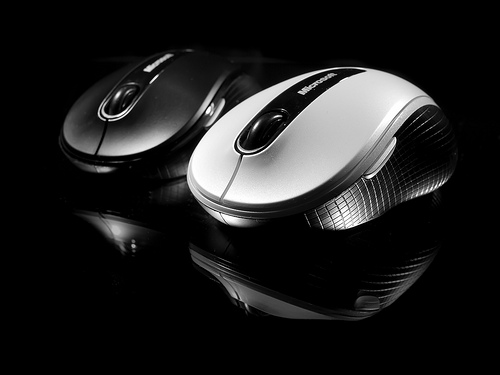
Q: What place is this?
A: It is a display.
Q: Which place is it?
A: It is a display.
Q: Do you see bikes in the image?
A: No, there are no bikes.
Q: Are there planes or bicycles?
A: No, there are no bicycles or planes.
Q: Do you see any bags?
A: No, there are no bags.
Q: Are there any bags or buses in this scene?
A: No, there are no bags or buses.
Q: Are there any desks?
A: Yes, there is a desk.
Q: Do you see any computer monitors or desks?
A: Yes, there is a desk.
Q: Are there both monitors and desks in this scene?
A: No, there is a desk but no monitors.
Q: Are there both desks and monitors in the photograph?
A: No, there is a desk but no monitors.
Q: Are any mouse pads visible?
A: No, there are no mouse pads.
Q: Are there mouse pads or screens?
A: No, there are no mouse pads or screens.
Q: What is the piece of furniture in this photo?
A: The piece of furniture is a desk.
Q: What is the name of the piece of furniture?
A: The piece of furniture is a desk.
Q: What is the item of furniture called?
A: The piece of furniture is a desk.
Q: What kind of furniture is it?
A: The piece of furniture is a desk.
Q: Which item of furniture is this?
A: This is a desk.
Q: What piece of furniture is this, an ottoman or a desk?
A: This is a desk.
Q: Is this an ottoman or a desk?
A: This is a desk.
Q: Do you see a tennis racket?
A: No, there are no rackets.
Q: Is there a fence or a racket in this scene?
A: No, there are no rackets or fences.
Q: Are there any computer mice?
A: Yes, there is a computer mouse.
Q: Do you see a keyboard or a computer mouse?
A: Yes, there is a computer mouse.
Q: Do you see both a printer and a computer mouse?
A: No, there is a computer mouse but no printers.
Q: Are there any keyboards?
A: No, there are no keyboards.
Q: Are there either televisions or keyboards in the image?
A: No, there are no keyboards or televisions.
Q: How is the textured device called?
A: The device is a computer mouse.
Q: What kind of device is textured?
A: The device is a computer mouse.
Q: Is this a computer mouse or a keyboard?
A: This is a computer mouse.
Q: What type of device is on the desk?
A: The device is a computer mouse.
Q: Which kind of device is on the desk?
A: The device is a computer mouse.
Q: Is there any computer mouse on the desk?
A: Yes, there is a computer mouse on the desk.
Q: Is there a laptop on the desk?
A: No, there is a computer mouse on the desk.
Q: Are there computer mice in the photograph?
A: Yes, there is a computer mouse.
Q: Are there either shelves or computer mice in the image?
A: Yes, there is a computer mouse.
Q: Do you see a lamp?
A: No, there are no lamps.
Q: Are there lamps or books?
A: No, there are no lamps or books.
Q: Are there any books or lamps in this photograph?
A: No, there are no lamps or books.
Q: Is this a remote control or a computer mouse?
A: This is a computer mouse.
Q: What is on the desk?
A: The mouse is on the desk.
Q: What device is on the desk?
A: The device is a computer mouse.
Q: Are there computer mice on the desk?
A: Yes, there is a computer mouse on the desk.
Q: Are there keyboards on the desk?
A: No, there is a computer mouse on the desk.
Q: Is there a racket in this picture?
A: No, there are no rackets.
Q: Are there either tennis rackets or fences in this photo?
A: No, there are no tennis rackets or fences.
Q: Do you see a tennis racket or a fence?
A: No, there are no rackets or fences.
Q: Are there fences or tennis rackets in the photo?
A: No, there are no tennis rackets or fences.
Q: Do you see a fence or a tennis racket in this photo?
A: No, there are no rackets or fences.